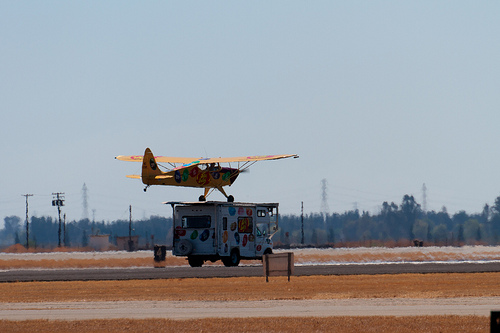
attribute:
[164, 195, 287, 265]
truck — colorful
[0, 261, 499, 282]
runway — dark grey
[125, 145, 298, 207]
plane — yellow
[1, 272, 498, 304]
grass — yellow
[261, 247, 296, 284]
sign — board 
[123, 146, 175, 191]
tail — orange 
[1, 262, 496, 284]
street — asphalt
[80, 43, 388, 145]
sky — blue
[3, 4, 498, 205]
sky — clear, blue and white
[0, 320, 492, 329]
grass — brown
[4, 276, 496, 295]
grass — brown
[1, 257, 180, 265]
grass — brown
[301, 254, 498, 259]
grass — brown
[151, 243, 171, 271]
can — trash  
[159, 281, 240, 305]
ground — brown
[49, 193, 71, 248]
poles — erected 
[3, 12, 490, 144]
sky — blue, clear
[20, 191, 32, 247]
pole — electricity 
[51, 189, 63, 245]
pole — electricity 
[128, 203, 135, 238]
pole — electricity 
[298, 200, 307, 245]
pole — electricity 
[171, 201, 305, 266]
truck — white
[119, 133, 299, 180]
wings — orange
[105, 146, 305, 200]
plane — small